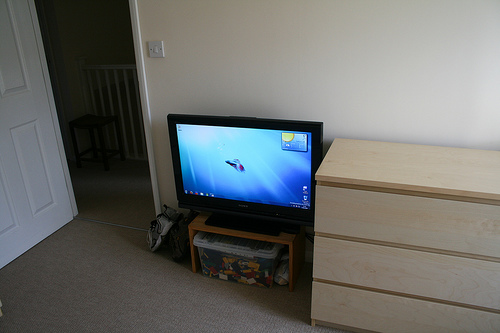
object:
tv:
[168, 112, 324, 221]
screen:
[176, 123, 314, 210]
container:
[192, 230, 286, 288]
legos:
[196, 247, 272, 286]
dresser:
[311, 135, 498, 321]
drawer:
[312, 182, 498, 259]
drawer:
[311, 233, 499, 313]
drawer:
[309, 280, 494, 328]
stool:
[68, 110, 128, 171]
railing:
[75, 60, 154, 160]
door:
[0, 0, 77, 270]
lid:
[192, 229, 285, 260]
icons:
[183, 189, 214, 200]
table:
[188, 211, 308, 290]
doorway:
[34, 0, 166, 233]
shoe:
[169, 223, 190, 265]